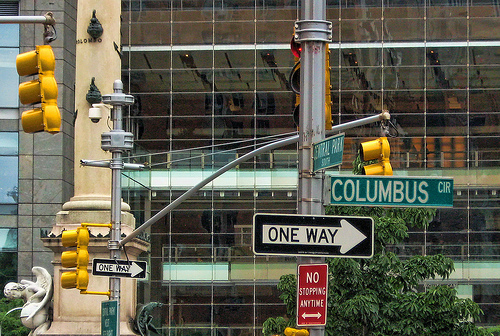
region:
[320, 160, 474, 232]
street sign for Columbus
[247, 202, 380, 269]
black and white one way sign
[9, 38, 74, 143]
hanging yellow street light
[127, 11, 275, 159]
large glass windows on a building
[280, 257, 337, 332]
red warning sign for no stopping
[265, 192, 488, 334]
green tree on the side of the road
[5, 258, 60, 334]
angel statue by the building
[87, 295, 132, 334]
green sign under the traffic light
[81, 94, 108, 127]
traffic camera watching the street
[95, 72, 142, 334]
metal pole holding lights up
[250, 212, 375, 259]
black and white sign on metal pole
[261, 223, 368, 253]
white arrow on black sign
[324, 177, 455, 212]
green street sign on pole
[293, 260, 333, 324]
red sign on pole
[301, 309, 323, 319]
arrow on red sign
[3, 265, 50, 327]
statue of an angel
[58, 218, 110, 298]
yellow traffic light on gray pole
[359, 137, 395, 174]
yellow traffic light is hanging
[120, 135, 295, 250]
metal arm supporting traffic light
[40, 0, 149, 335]
tall stone column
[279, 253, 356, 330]
red and white square sign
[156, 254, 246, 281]
light green partition on wall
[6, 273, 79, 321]
white ange statue on side of building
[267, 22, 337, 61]
red light on traffic signal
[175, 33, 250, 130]
clear iron on tall building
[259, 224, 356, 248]
black words in white arrow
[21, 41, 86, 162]
yellow traffic light signal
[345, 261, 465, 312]
large green tree in front of building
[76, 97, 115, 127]
white domed light on post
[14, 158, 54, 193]
gray tiles on wall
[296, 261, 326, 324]
Red sign on a pole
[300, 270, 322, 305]
Words on the red sign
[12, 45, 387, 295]
Yellow traffic lights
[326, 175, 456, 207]
Road sign says Columbus CIR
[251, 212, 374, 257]
One Way sign on a pole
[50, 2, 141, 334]
Pillar in front of a building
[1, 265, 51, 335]
White statue next to the pillar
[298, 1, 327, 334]
Pole with many signs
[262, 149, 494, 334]
Trees in front of a building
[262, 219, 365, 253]
White arrow on the black sign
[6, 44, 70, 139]
A traffic signal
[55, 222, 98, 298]
A traffic signal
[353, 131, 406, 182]
Part of a traffic signal.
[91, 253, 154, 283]
A one way traffic sign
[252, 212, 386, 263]
A one way traffic sign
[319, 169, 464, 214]
A sign with a street name.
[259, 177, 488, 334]
A green leafy tree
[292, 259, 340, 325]
A no stopping sign.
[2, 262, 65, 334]
An angel statue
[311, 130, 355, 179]
A sign with a street name.